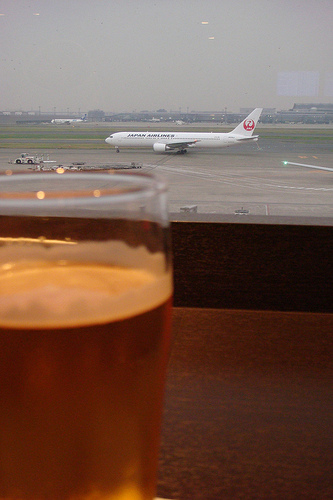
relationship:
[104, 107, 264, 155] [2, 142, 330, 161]
airplane on runway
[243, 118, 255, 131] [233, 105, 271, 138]
logo on tail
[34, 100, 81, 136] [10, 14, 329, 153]
plane in background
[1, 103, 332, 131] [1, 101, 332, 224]
scenery at airport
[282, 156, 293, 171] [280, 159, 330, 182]
light on wing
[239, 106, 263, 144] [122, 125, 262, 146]
logo on plane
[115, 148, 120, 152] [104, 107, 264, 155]
wheels at front of airplane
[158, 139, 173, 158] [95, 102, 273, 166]
engine on side of plane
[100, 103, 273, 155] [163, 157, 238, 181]
airplane on ground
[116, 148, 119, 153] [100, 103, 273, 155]
wheels of airplane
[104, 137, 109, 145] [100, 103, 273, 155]
nose of airplane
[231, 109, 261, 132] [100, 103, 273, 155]
wing of airplane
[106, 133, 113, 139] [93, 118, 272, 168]
cockpit of airplane